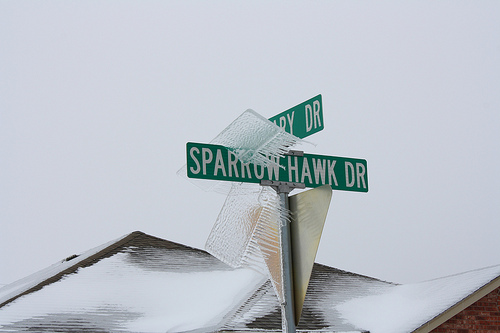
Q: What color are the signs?
A: Green.